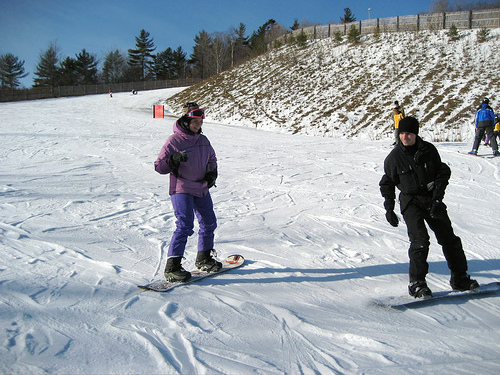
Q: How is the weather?
A: Cold.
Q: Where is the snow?
A: On the ground.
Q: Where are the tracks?
A: In the snow.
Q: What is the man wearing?
A: Snow suit.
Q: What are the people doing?
A: Snowboarding.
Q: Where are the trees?
A: In the distance.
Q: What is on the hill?
A: Snow and grass.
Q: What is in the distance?
A: Trees.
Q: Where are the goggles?
A: On woman's forehead.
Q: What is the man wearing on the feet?
A: Snowboard.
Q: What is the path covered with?
A: Snow.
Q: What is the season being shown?
A: Winter.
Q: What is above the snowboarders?
A: The clear blue sky.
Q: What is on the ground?
A: A shadow.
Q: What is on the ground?
A: The snow.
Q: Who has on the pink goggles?
A: Female on snowboard.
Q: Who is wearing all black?
A: Person to right on snowboard.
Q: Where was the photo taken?
A: Snowy hill.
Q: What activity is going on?
A: Snowboarding.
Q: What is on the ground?
A: Snow.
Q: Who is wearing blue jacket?
A: Person in background.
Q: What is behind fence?
A: Trees.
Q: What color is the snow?
A: White.